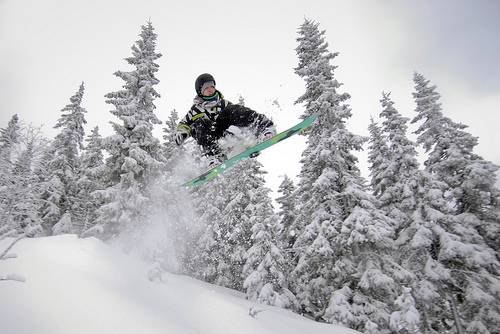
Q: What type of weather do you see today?
A: It is cloudy.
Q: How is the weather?
A: It is cloudy.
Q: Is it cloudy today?
A: Yes, it is cloudy.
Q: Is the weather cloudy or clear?
A: It is cloudy.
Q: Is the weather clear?
A: No, it is cloudy.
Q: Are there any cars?
A: No, there are no cars.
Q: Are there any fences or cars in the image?
A: No, there are no cars or fences.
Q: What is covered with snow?
A: The trees are covered with snow.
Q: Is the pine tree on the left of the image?
A: Yes, the pine tree is on the left of the image.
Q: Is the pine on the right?
A: No, the pine is on the left of the image.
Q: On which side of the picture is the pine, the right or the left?
A: The pine is on the left of the image.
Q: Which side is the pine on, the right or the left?
A: The pine is on the left of the image.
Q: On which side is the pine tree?
A: The pine tree is on the left of the image.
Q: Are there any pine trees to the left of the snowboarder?
A: Yes, there is a pine tree to the left of the snowboarder.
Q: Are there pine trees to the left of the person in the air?
A: Yes, there is a pine tree to the left of the snowboarder.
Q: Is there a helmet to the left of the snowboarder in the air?
A: No, there is a pine tree to the left of the snowboarder.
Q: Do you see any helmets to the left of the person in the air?
A: No, there is a pine tree to the left of the snowboarder.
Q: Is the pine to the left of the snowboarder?
A: Yes, the pine is to the left of the snowboarder.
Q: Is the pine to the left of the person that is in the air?
A: Yes, the pine is to the left of the snowboarder.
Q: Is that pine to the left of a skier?
A: No, the pine is to the left of the snowboarder.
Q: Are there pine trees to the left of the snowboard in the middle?
A: Yes, there is a pine tree to the left of the snowboard.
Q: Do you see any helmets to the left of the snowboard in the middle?
A: No, there is a pine tree to the left of the snowboard.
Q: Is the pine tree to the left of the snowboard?
A: Yes, the pine tree is to the left of the snowboard.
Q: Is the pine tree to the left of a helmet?
A: No, the pine tree is to the left of the snowboard.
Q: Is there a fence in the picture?
A: No, there are no fences.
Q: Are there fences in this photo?
A: No, there are no fences.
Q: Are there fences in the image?
A: No, there are no fences.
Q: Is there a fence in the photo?
A: No, there are no fences.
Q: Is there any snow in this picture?
A: Yes, there is snow.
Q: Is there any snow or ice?
A: Yes, there is snow.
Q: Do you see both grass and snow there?
A: No, there is snow but no grass.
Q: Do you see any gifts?
A: No, there are no gifts.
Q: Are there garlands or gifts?
A: No, there are no gifts or garlands.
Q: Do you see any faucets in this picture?
A: No, there are no faucets.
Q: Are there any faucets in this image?
A: No, there are no faucets.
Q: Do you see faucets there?
A: No, there are no faucets.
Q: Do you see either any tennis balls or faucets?
A: No, there are no faucets or tennis balls.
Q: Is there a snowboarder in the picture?
A: Yes, there is a snowboarder.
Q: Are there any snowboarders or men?
A: Yes, there is a snowboarder.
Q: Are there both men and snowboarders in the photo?
A: No, there is a snowboarder but no men.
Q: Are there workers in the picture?
A: No, there are no workers.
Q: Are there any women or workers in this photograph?
A: No, there are no workers or women.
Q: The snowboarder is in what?
A: The snowboarder is in the air.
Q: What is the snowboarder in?
A: The snowboarder is in the air.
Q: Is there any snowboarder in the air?
A: Yes, there is a snowboarder in the air.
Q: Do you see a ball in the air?
A: No, there is a snowboarder in the air.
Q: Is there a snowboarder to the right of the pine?
A: Yes, there is a snowboarder to the right of the pine.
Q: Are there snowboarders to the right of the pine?
A: Yes, there is a snowboarder to the right of the pine.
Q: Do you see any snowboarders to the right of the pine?
A: Yes, there is a snowboarder to the right of the pine.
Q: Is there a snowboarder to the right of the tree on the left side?
A: Yes, there is a snowboarder to the right of the pine.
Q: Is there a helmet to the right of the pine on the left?
A: No, there is a snowboarder to the right of the pine tree.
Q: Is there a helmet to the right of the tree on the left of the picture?
A: No, there is a snowboarder to the right of the pine tree.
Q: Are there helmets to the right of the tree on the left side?
A: No, there is a snowboarder to the right of the pine tree.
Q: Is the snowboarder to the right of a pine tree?
A: Yes, the snowboarder is to the right of a pine tree.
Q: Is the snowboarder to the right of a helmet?
A: No, the snowboarder is to the right of a pine tree.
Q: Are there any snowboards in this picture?
A: Yes, there is a snowboard.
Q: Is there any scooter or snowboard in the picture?
A: Yes, there is a snowboard.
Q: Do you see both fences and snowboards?
A: No, there is a snowboard but no fences.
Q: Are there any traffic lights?
A: No, there are no traffic lights.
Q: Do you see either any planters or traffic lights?
A: No, there are no traffic lights or planters.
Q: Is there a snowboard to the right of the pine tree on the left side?
A: Yes, there is a snowboard to the right of the pine.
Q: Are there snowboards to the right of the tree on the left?
A: Yes, there is a snowboard to the right of the pine.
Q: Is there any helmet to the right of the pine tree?
A: No, there is a snowboard to the right of the pine tree.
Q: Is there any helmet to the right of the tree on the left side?
A: No, there is a snowboard to the right of the pine tree.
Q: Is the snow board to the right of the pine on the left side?
A: Yes, the snow board is to the right of the pine tree.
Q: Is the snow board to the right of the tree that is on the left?
A: Yes, the snow board is to the right of the pine tree.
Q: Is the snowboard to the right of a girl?
A: No, the snowboard is to the right of the pine tree.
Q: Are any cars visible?
A: No, there are no cars.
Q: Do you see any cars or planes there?
A: No, there are no cars or planes.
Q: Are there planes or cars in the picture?
A: No, there are no cars or planes.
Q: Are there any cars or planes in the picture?
A: No, there are no cars or planes.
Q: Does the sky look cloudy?
A: Yes, the sky is cloudy.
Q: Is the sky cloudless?
A: No, the sky is cloudy.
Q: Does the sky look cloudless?
A: No, the sky is cloudy.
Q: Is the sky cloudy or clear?
A: The sky is cloudy.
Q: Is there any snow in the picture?
A: Yes, there is snow.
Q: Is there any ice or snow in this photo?
A: Yes, there is snow.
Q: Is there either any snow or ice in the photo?
A: Yes, there is snow.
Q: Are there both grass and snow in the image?
A: No, there is snow but no grass.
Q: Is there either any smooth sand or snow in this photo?
A: Yes, there is smooth snow.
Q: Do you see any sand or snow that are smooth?
A: Yes, the snow is smooth.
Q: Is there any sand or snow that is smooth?
A: Yes, the snow is smooth.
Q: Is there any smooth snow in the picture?
A: Yes, there is smooth snow.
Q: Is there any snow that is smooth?
A: Yes, there is snow that is smooth.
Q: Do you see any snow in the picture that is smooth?
A: Yes, there is snow that is smooth.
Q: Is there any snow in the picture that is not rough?
A: Yes, there is smooth snow.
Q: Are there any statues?
A: No, there are no statues.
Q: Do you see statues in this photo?
A: No, there are no statues.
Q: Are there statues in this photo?
A: No, there are no statues.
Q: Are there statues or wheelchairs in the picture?
A: No, there are no statues or wheelchairs.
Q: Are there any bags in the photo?
A: No, there are no bags.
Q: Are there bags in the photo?
A: No, there are no bags.